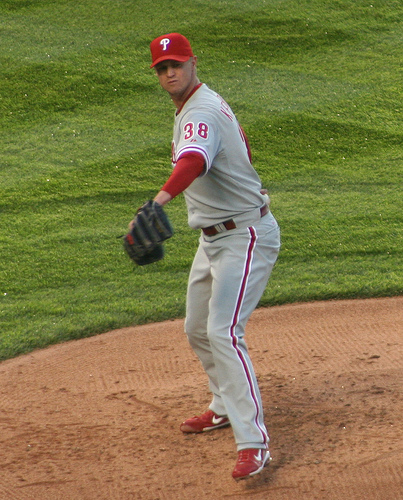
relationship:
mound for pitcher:
[7, 299, 402, 498] [117, 31, 318, 487]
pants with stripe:
[180, 228, 299, 450] [229, 226, 271, 452]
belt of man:
[200, 202, 274, 238] [122, 21, 310, 481]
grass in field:
[3, 2, 402, 291] [6, 4, 402, 499]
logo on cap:
[159, 35, 173, 55] [145, 32, 193, 66]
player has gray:
[117, 31, 318, 487] [244, 165, 245, 171]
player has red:
[117, 31, 318, 487] [187, 163, 189, 166]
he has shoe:
[117, 31, 318, 487] [226, 447, 282, 483]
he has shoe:
[117, 31, 318, 487] [176, 408, 233, 436]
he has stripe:
[117, 31, 318, 487] [229, 226, 271, 452]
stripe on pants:
[229, 226, 271, 452] [180, 228, 299, 450]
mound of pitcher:
[7, 299, 402, 498] [117, 31, 318, 487]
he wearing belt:
[117, 31, 318, 487] [200, 202, 274, 238]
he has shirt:
[117, 31, 318, 487] [159, 152, 207, 205]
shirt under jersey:
[159, 152, 207, 205] [171, 90, 267, 223]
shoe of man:
[226, 447, 282, 483] [122, 21, 310, 481]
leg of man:
[206, 234, 303, 481] [122, 21, 310, 481]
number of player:
[182, 118, 213, 146] [117, 31, 318, 487]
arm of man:
[118, 112, 225, 233] [122, 21, 310, 481]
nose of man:
[163, 68, 178, 82] [122, 21, 310, 481]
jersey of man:
[171, 90, 267, 223] [122, 21, 310, 481]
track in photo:
[248, 334, 385, 368] [2, 1, 400, 499]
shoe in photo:
[226, 447, 282, 483] [2, 1, 400, 499]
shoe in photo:
[176, 408, 233, 436] [2, 1, 400, 499]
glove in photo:
[109, 200, 184, 268] [2, 1, 400, 499]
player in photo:
[117, 31, 318, 487] [2, 1, 400, 499]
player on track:
[117, 31, 318, 487] [248, 334, 385, 368]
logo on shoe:
[254, 449, 266, 462] [226, 447, 282, 483]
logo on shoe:
[210, 414, 226, 426] [176, 408, 233, 436]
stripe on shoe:
[254, 449, 266, 462] [226, 447, 282, 483]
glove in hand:
[109, 200, 184, 268] [125, 209, 162, 226]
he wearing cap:
[117, 31, 318, 487] [145, 32, 193, 66]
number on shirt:
[182, 118, 213, 146] [171, 90, 267, 223]